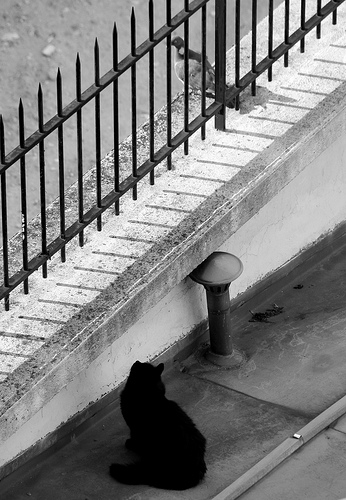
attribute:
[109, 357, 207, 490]
cat — black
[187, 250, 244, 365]
pipe — grey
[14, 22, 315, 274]
fence — black, iron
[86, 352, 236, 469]
cat — black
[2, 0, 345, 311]
bars — sharp, metallic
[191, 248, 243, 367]
pipe — vent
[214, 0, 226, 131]
bar — black, iron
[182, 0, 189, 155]
bar — black, iron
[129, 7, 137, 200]
bar — black, iron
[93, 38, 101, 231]
bar — black, iron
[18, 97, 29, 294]
bar — black, iron